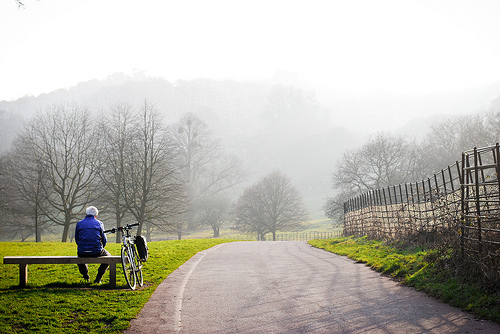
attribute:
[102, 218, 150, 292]
bike — leaning, upright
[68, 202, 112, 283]
man — sitting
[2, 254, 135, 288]
bench — backless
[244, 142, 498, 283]
fence — wooden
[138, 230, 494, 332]
road — gray, cracked, curved, asphalt, paved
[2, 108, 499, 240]
trees — large, foggy, bare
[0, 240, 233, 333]
grass — green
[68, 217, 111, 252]
coat — blue, purple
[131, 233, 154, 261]
bag — dark, black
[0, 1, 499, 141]
sky — overcast, foggy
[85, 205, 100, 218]
hair — white